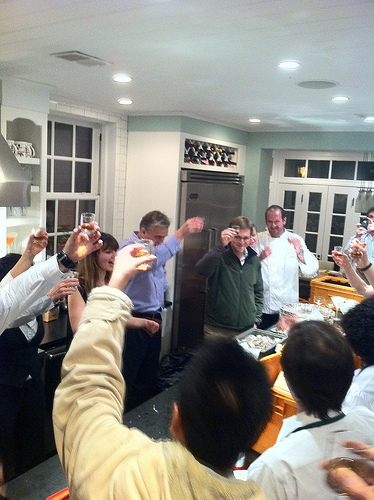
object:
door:
[172, 167, 244, 354]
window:
[46, 112, 100, 256]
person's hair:
[139, 210, 173, 234]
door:
[265, 150, 374, 272]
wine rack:
[184, 138, 239, 167]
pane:
[74, 123, 93, 161]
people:
[0, 204, 374, 499]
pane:
[332, 192, 349, 216]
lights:
[112, 61, 374, 125]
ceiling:
[0, 0, 374, 132]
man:
[0, 205, 374, 500]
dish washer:
[44, 345, 69, 457]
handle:
[46, 346, 67, 357]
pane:
[54, 122, 74, 158]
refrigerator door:
[176, 185, 241, 345]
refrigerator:
[172, 169, 245, 351]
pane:
[283, 190, 295, 210]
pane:
[282, 210, 295, 231]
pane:
[307, 190, 323, 213]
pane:
[306, 213, 320, 234]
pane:
[305, 231, 317, 253]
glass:
[130, 236, 157, 270]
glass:
[80, 212, 97, 235]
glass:
[32, 226, 45, 243]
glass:
[334, 245, 343, 263]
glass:
[232, 225, 240, 235]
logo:
[189, 193, 198, 199]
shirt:
[116, 230, 181, 314]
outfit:
[252, 228, 319, 330]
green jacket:
[195, 244, 264, 334]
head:
[168, 334, 276, 474]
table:
[42, 303, 374, 499]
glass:
[196, 213, 205, 221]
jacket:
[51, 283, 265, 500]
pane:
[72, 159, 93, 196]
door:
[44, 116, 101, 257]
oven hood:
[0, 134, 34, 207]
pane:
[330, 213, 346, 237]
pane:
[327, 236, 344, 256]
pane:
[57, 198, 78, 233]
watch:
[56, 249, 79, 269]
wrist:
[53, 249, 75, 272]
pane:
[182, 178, 209, 339]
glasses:
[32, 212, 240, 271]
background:
[0, 89, 374, 261]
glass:
[231, 225, 240, 233]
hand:
[109, 243, 157, 286]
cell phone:
[360, 211, 369, 229]